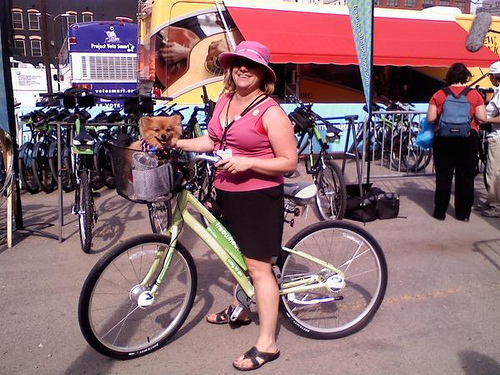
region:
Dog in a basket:
[97, 112, 192, 202]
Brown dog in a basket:
[100, 109, 184, 205]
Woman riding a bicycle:
[72, 39, 389, 372]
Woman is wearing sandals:
[206, 297, 286, 372]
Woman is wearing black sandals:
[205, 299, 282, 373]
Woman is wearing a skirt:
[203, 184, 287, 259]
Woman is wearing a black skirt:
[208, 180, 288, 261]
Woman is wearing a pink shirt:
[205, 86, 290, 191]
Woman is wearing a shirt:
[205, 85, 288, 188]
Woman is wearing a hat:
[212, 38, 283, 81]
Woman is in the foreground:
[154, 38, 324, 374]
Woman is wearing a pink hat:
[208, 29, 285, 90]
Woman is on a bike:
[73, 132, 408, 364]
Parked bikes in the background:
[14, 85, 429, 248]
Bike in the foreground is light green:
[136, 180, 307, 332]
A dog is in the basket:
[113, 108, 195, 200]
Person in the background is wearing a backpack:
[419, 55, 489, 227]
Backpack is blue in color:
[434, 90, 477, 146]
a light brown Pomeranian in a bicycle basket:
[122, 115, 179, 202]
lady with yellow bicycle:
[75, 43, 388, 369]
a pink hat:
[212, 42, 272, 82]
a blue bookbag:
[437, 87, 472, 138]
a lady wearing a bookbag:
[422, 60, 489, 224]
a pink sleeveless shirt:
[205, 83, 280, 190]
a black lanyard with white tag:
[214, 87, 272, 163]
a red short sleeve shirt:
[428, 86, 485, 130]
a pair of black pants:
[429, 128, 481, 218]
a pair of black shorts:
[212, 188, 286, 263]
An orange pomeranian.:
[126, 115, 182, 167]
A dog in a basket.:
[105, 107, 185, 197]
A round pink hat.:
[215, 35, 277, 80]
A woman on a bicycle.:
[72, 42, 392, 362]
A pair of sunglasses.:
[230, 56, 255, 66]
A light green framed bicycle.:
[74, 154, 393, 366]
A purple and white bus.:
[55, 19, 147, 106]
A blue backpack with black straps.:
[440, 87, 475, 139]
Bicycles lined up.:
[19, 90, 428, 254]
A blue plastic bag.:
[418, 116, 436, 153]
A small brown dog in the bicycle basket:
[129, 113, 187, 184]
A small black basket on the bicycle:
[105, 146, 190, 199]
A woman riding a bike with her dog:
[117, 35, 408, 357]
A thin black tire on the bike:
[86, 229, 198, 344]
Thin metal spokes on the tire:
[105, 255, 179, 342]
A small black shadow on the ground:
[460, 346, 495, 373]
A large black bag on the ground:
[337, 180, 407, 222]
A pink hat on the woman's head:
[226, 40, 280, 77]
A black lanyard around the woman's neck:
[217, 88, 272, 140]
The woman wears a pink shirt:
[211, 87, 280, 186]